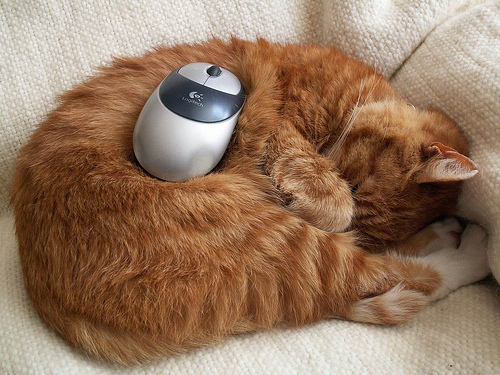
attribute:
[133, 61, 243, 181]
mouse — gray, black, silver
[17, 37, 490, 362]
cat — sleeping, brown, striped, fluffy, hiding, orange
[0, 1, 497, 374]
couch — white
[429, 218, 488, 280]
toes — white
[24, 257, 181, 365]
tail — brown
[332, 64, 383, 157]
whiskers — white, long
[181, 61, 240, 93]
buttons — gray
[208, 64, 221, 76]
scroll-wheel — black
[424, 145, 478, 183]
ears — orange, hairy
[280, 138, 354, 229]
paw — orange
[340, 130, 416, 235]
face — orange